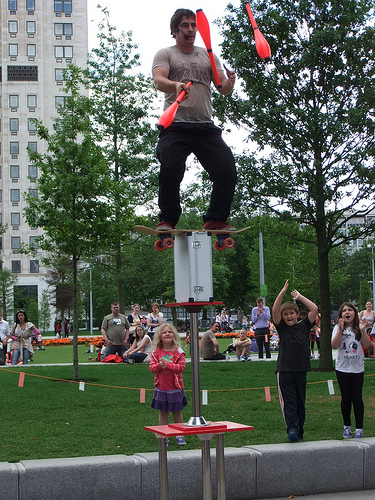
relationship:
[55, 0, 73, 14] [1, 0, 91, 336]
window on building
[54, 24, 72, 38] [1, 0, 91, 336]
window on building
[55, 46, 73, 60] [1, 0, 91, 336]
window on building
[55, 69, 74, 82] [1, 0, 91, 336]
window on building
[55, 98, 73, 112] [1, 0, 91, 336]
window on building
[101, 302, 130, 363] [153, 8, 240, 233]
man watching juggler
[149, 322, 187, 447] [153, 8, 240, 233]
girl watching juggler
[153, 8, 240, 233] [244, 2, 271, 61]
juggler juggling juggling pin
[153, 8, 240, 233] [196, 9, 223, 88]
juggler juggling juggling pin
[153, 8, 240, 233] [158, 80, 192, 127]
juggler juggling juggling pin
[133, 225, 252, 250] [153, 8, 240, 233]
skateboard under juggler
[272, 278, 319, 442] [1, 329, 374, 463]
boy standing in grass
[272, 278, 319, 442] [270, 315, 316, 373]
boy in a shirt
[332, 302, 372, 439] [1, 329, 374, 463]
girl standing in grass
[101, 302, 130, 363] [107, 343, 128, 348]
man has pockets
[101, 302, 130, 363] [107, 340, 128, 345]
man has hands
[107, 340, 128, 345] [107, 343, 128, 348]
hands in pockets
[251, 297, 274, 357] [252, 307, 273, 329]
man in a shirt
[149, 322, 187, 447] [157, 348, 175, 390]
girl has shirt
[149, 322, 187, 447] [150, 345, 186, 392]
girl has jacket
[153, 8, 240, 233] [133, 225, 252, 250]
juggler balancing on skateboard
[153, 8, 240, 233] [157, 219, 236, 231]
juggler wearing shoes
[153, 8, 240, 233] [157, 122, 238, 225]
juggler wearing pants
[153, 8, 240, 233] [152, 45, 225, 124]
juggler wearing shirt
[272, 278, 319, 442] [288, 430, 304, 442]
boy wearing shoes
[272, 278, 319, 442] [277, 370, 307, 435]
boy wearing pants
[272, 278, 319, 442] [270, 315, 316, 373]
boy wearing shirt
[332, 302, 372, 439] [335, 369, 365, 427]
girl wearing leggings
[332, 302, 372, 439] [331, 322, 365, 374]
girl wearing shirt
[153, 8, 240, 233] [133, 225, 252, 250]
juggler standing on skateboard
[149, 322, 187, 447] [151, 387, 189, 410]
girl wearing skirt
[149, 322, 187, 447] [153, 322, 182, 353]
girl has hair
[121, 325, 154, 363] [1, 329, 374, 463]
woman sitting on grass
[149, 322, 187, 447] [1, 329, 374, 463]
girl standing on grass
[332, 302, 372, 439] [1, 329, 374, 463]
girl standing on grass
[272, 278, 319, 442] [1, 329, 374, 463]
boy standing on grass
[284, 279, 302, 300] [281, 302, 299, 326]
hands above head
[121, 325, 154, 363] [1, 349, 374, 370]
woman on sidewalk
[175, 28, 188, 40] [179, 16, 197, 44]
microphone on face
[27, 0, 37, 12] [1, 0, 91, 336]
window on building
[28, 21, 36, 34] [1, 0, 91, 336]
window on building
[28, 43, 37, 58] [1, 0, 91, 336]
window on building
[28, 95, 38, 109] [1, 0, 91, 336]
window on building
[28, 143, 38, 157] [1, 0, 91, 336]
window on building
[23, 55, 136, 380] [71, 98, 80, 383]
tree has trunk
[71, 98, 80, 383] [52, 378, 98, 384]
trunk sticking out of dirt